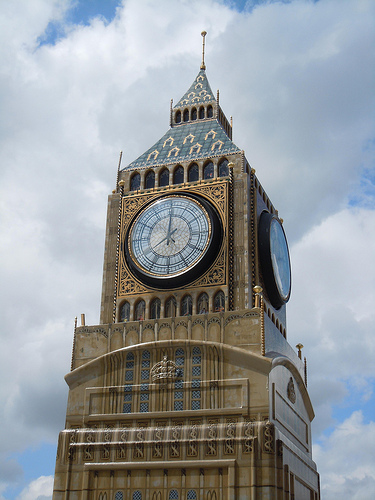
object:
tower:
[50, 30, 321, 498]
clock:
[125, 193, 213, 282]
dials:
[274, 256, 290, 265]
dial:
[166, 210, 171, 245]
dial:
[149, 219, 179, 249]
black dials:
[128, 196, 210, 279]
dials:
[274, 245, 286, 260]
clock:
[256, 209, 291, 311]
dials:
[153, 227, 176, 254]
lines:
[177, 246, 189, 268]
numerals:
[135, 216, 153, 233]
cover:
[267, 215, 294, 300]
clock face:
[131, 192, 212, 278]